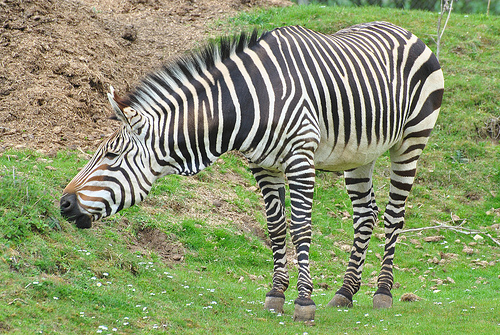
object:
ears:
[107, 91, 150, 135]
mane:
[126, 22, 271, 117]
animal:
[54, 15, 446, 325]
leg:
[328, 162, 377, 307]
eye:
[102, 151, 119, 160]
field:
[1, 1, 497, 333]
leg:
[256, 163, 292, 308]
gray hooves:
[260, 290, 285, 314]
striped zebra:
[59, 19, 446, 320]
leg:
[371, 120, 427, 306]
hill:
[4, 8, 120, 74]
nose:
[59, 193, 77, 214]